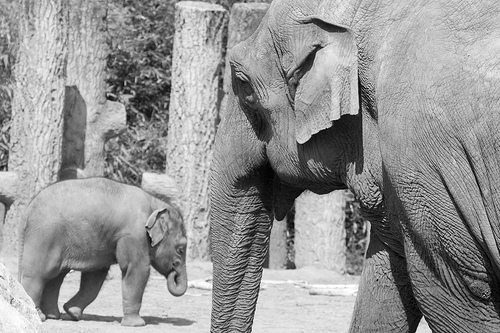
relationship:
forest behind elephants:
[81, 2, 174, 174] [23, 1, 498, 319]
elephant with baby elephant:
[206, 0, 499, 333] [12, 172, 191, 332]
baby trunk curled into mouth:
[164, 261, 191, 296] [165, 259, 175, 277]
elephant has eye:
[187, 3, 484, 331] [229, 62, 258, 100]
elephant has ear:
[187, 3, 484, 331] [277, 8, 367, 148]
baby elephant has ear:
[18, 175, 188, 327] [137, 205, 179, 240]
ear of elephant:
[277, 15, 360, 144] [187, 3, 484, 331]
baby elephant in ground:
[18, 175, 188, 327] [152, 304, 207, 328]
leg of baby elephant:
[113, 228, 150, 319] [18, 175, 188, 327]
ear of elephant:
[277, 21, 365, 144] [209, 0, 498, 330]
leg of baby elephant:
[116, 228, 150, 325] [18, 175, 188, 327]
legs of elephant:
[17, 219, 75, 317] [12, 164, 218, 331]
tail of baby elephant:
[13, 206, 34, 289] [18, 175, 188, 327]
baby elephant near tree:
[18, 175, 188, 327] [145, 3, 236, 271]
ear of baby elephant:
[145, 207, 173, 247] [12, 172, 191, 332]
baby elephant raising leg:
[18, 175, 188, 327] [62, 266, 108, 322]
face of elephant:
[213, 3, 354, 212] [187, 3, 484, 331]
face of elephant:
[146, 194, 188, 301] [17, 160, 197, 308]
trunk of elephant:
[196, 165, 273, 330] [187, 3, 484, 331]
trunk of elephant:
[164, 261, 189, 296] [6, 166, 195, 316]